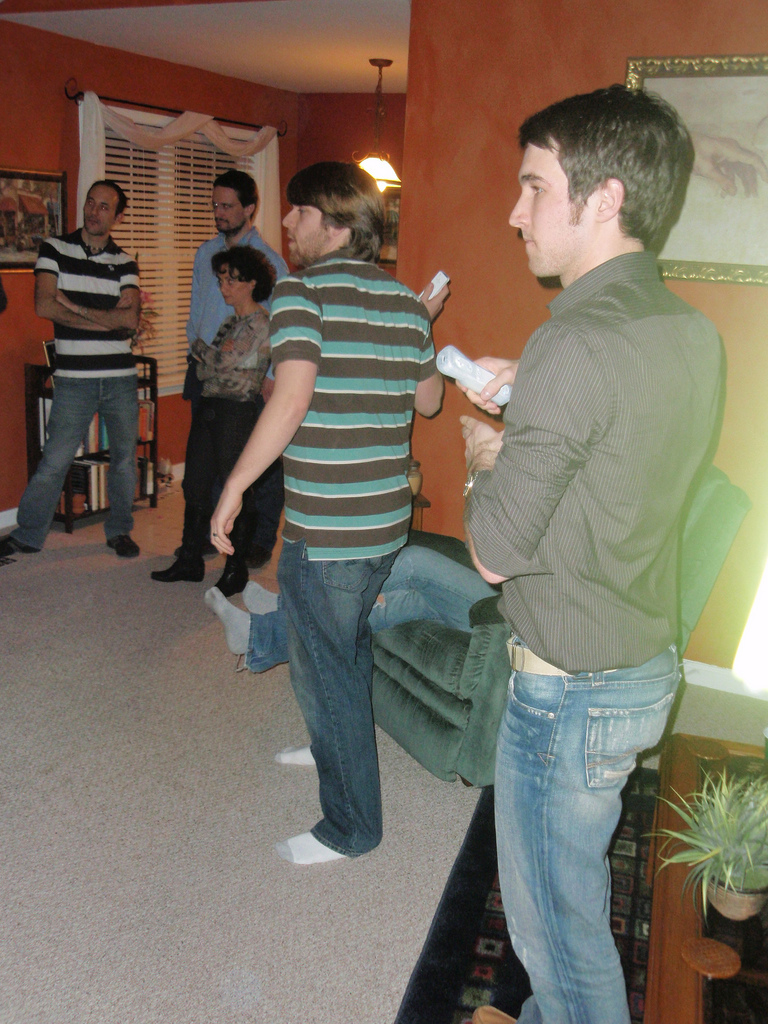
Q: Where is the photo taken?
A: In a house.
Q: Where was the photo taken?
A: In a living room.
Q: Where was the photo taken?
A: In a entertainment room.